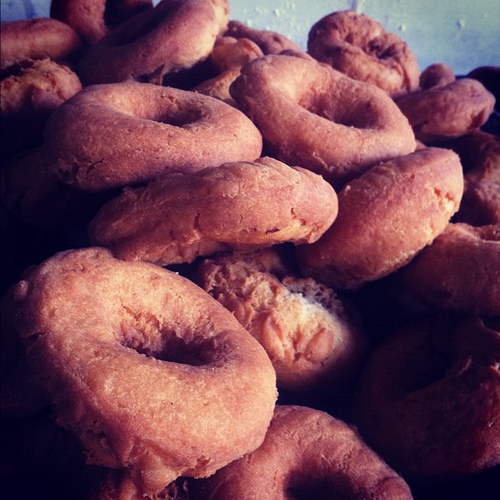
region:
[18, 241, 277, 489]
a fried donut on a pile.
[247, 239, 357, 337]
toppings on a donut.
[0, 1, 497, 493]
a pile of fried donuts.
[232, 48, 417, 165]
donuts on a pile.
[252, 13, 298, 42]
donut crumbs on a counter.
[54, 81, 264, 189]
a donut laying on another donut.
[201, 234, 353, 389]
a donut with frosting on it.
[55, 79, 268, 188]
a fried to perfection donut.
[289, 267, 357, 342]
odd white topping.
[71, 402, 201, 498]
deformed donut.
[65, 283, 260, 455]
plain round donut with hole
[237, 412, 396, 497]
plain round donut with hole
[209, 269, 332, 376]
plain round donut with hole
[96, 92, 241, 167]
plain round donut with hole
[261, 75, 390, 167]
plain round donut with hole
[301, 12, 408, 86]
plain round donut with hole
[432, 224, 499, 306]
plain round donut with hole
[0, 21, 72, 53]
plain round donut with hole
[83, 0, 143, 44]
plain round donut with hole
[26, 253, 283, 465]
Brown doughnut with hole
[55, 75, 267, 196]
Brown doughnut on top of other doughnuts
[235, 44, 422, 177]
Brown doughnut with hole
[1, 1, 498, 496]
Mountain of doughnuts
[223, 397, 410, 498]
Plain brown doughnuts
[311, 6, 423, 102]
Crusty brown doughnuts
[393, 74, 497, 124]
Lots of brown doughnuts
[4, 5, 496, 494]
Doughnuts piled on each other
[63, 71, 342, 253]
Doughnut on top of doughnut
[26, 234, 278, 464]
Plain doughnut with hole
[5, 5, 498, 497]
A photograph of donuts.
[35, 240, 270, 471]
The donut is biege in color.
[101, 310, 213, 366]
The hole of the donut.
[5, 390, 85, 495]
A shadow next to the donut.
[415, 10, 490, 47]
The wall is light blue.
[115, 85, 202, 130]
The shadow inside the donut hole.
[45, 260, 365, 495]
Two donuts side by side.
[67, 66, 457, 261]
Four donuts next to each other.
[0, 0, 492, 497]
A pile of donuts.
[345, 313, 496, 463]
A donut in the shadows.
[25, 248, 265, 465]
a plain brown fried donut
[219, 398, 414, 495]
a plain brown fried donut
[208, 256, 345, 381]
a plain brown fried donut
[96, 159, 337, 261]
a plain brown fried donut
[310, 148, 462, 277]
a plain brown fried donut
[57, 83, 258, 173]
a plain brown fried donut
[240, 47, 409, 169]
a plain brown fried donut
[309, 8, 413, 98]
a plain brown fried donut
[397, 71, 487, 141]
a plain brown fried donut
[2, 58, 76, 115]
a plain brown fried donut